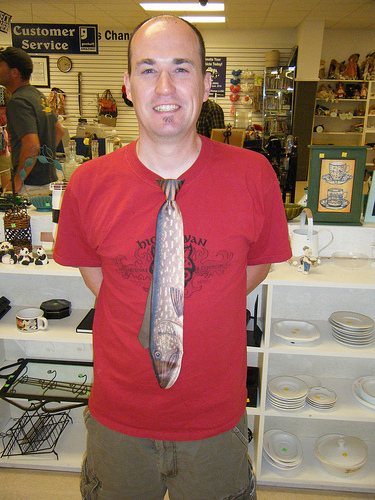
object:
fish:
[147, 178, 187, 388]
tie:
[149, 178, 187, 392]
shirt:
[53, 135, 293, 440]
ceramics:
[267, 311, 371, 475]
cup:
[15, 306, 48, 332]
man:
[53, 15, 294, 500]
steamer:
[2, 409, 70, 460]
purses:
[97, 112, 117, 129]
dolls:
[311, 48, 374, 146]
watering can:
[284, 207, 331, 272]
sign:
[11, 22, 99, 56]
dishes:
[263, 307, 374, 473]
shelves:
[262, 255, 375, 500]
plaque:
[315, 155, 355, 213]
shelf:
[274, 279, 373, 295]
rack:
[1, 396, 73, 461]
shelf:
[15, 305, 50, 335]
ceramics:
[1, 242, 51, 266]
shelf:
[0, 256, 90, 281]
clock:
[57, 55, 75, 74]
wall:
[40, 43, 126, 127]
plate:
[273, 317, 319, 346]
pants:
[78, 410, 264, 500]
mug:
[16, 306, 49, 331]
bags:
[48, 88, 120, 126]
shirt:
[6, 85, 58, 188]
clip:
[159, 178, 182, 200]